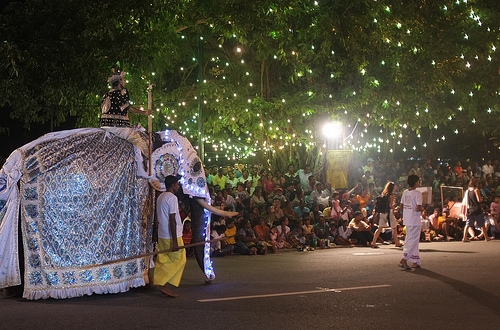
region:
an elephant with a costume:
[18, 58, 301, 328]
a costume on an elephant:
[18, 80, 267, 328]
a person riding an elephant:
[17, 41, 350, 324]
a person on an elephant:
[12, 25, 264, 320]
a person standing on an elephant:
[21, 71, 305, 310]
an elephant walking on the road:
[44, 34, 340, 329]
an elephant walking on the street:
[29, 66, 310, 329]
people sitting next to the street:
[177, 125, 472, 255]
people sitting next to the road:
[187, 134, 358, 231]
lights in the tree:
[54, 8, 483, 214]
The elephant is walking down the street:
[1, 45, 471, 320]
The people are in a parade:
[11, 28, 496, 300]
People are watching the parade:
[5, 22, 496, 294]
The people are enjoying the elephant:
[0, 33, 496, 293]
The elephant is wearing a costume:
[18, 8, 243, 320]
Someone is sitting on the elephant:
[6, 25, 246, 316]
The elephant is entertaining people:
[10, 28, 255, 308]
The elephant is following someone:
[2, 36, 497, 301]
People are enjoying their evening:
[7, 17, 488, 308]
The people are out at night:
[9, 32, 494, 307]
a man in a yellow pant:
[157, 234, 183, 284]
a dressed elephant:
[20, 123, 215, 305]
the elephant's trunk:
[190, 196, 220, 279]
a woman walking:
[403, 175, 422, 262]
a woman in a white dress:
[403, 178, 423, 263]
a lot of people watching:
[232, 183, 379, 247]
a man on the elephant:
[101, 63, 159, 176]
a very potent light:
[321, 121, 346, 141]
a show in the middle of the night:
[3, 47, 498, 304]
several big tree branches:
[164, 42, 466, 124]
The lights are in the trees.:
[61, 13, 490, 162]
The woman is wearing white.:
[394, 178, 429, 263]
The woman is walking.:
[390, 162, 432, 276]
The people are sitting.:
[205, 164, 497, 241]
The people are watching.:
[187, 166, 497, 231]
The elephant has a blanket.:
[8, 130, 222, 319]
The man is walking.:
[149, 182, 189, 302]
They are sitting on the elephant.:
[103, 66, 164, 167]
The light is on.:
[315, 113, 349, 143]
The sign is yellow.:
[324, 148, 351, 191]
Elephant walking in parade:
[21, 37, 463, 318]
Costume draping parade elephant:
[4, 113, 230, 302]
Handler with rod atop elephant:
[91, 58, 216, 184]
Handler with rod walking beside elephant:
[134, 167, 226, 299]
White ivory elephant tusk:
[198, 191, 240, 221]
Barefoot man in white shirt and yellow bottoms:
[140, 175, 192, 307]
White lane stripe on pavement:
[193, 281, 400, 310]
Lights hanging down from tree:
[175, 33, 494, 155]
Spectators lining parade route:
[211, 160, 373, 245]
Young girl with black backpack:
[369, 182, 399, 249]